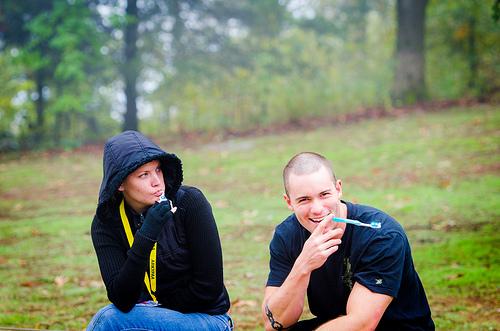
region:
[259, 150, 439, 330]
man holding a blue tooth brush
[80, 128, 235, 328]
girl holding a blue tooth brush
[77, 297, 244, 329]
blue denim pants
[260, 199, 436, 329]
wrinkly black tee shirt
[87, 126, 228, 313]
black hooded coat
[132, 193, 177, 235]
knitted black fingerless gloves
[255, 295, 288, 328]
black tattoo on man's arm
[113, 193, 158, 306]
bright yellow lanyard around girl's neck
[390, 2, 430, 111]
thick light brown tree trunk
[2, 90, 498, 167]
dead leaves along the tree line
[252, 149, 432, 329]
a guy holding his toothbrush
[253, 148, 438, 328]
a bald guy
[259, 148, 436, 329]
a guy in blue shirt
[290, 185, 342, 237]
a facial expression of the guy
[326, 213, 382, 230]
a toothbrush the is holding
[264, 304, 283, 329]
a tattoo on the arm of the guy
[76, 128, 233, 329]
a person wearing a hoodie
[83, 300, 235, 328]
jeans the person is wearing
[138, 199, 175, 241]
a glove on the hand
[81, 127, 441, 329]
two people in the outdoor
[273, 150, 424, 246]
a man holding a toothbrush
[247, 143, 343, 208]
a man with short hair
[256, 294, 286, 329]
a man with a tatoo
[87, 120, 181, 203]
a woman wearing a hood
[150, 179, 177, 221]
a woman with a toothbrush in her mouth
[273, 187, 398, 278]
a man wearing a blue shirt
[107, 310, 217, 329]
a woman wearing blue jeans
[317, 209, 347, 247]
a man with the wrong end of a toothbrush in his mouth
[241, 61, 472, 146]
brown leaves on the ground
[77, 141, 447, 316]
a man and woman sitting next to each other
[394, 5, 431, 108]
the trunk of the tree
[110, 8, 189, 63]
the sky through the branches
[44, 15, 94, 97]
leaves off the tree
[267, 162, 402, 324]
a man wearing a blue shirt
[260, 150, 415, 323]
a man holding a blue toothbrush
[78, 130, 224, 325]
a lady brushing her teeth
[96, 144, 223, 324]
a woman wearing a yellow necklace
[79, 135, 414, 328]
a man and a woman sitting down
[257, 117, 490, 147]
leaves on the ground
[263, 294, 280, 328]
a tattoo on the mans arm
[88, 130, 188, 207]
Woman wearing a hoodie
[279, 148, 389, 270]
Man holding a toothbrush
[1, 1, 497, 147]
Trees are in the background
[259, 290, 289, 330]
Tattoo on man's arm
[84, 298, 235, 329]
A pair of blue jeans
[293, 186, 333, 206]
A pair of eyes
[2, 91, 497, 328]
Leaves on a grass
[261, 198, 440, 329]
A navy blue short sleeved shirt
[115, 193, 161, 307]
A yellow string around woman's neck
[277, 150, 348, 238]
The man is smiling